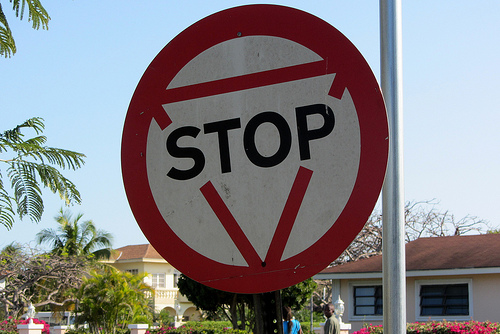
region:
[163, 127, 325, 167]
STOP is written in black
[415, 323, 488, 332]
pink flowers on the bush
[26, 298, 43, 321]
statue on the stand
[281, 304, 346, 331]
people in front of the tree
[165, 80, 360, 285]
stop sign is round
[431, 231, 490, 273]
roof is red on the house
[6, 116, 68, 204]
palm leaves over the tree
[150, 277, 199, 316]
balcony on the house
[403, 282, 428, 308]
white trim around the window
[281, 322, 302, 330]
woman has a pony tail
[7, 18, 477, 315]
this is a stop sign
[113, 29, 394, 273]
this stop sign has a triangle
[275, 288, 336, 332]
these are people on the other side of the stop sign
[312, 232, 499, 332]
this is a house on the street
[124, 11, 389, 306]
this is a sign on the street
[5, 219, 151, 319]
trees along the city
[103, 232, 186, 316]
a building in the area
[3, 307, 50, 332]
colorful flowers in the distance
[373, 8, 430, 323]
a pole next to the stop sign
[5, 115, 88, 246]
a palm tree leaf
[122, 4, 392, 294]
Red, white and black round stop sign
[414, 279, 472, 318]
Window with six slats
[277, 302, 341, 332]
Two people standing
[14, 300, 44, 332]
White column with top decoration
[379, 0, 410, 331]
Metal pole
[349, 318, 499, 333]
Bush with pink flowers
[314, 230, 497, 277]
Brown roof on a house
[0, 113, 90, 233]
Leaves on a palm-like tree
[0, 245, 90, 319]
Tree with no leaves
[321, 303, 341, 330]
Black man wearing a green shirt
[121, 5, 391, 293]
Circle sign that says stop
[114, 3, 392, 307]
Sign outlined in red with white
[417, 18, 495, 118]
Clear sunny day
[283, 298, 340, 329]
Two people looking at camera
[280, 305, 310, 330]
Individual with pony tail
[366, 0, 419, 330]
Silver metal pole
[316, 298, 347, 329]
Male wearing green top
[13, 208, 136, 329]
Green trees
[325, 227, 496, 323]
Beige house with brown roof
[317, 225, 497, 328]
Beige home with two windows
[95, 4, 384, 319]
the sign is circular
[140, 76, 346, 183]
the word says stop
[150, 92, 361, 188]
the letters are black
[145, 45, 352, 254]
a triangle inside the circle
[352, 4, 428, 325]
the pole is tall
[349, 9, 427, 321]
the pole is silver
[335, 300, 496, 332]
the flowers are pink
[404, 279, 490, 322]
the windows are open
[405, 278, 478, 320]
the windows are black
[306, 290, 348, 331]
boy is looking at the camera